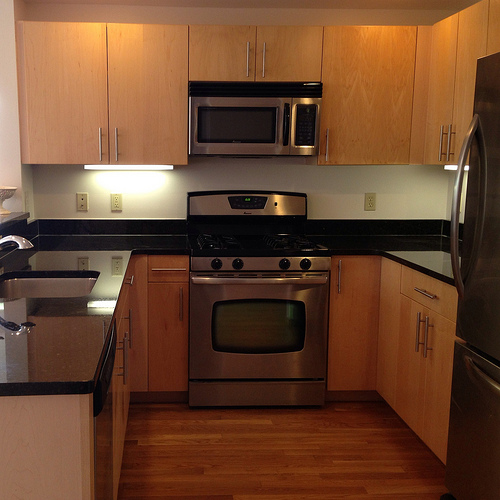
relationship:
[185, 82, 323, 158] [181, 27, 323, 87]
microwave under cabinets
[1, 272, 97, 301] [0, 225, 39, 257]
sink and faucet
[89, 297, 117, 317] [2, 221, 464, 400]
reflections on counter top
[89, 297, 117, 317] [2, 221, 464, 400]
reflection on counter top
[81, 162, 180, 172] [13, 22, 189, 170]
light under cabinet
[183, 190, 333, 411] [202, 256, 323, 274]
oven has knobs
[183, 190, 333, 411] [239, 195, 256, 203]
oven has a display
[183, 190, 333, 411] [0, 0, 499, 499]
stove in kitchen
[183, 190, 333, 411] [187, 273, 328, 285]
oven has handle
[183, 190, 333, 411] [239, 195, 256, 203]
stove time display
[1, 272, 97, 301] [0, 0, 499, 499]
sink on kitchen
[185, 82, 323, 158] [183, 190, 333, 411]
microwave above oven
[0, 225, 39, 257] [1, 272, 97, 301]
faucet above sink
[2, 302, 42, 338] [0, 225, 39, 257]
reflection of faucet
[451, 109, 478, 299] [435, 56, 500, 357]
handle to fridge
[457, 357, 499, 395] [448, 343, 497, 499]
handle to freezer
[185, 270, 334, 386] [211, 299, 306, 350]
door has window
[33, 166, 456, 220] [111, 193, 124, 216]
wall has outlet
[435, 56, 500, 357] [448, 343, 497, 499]
refrigerator with freezer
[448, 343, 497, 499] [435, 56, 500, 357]
freezer beneath refrigerator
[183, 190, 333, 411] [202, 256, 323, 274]
stove has knobs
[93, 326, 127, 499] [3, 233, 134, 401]
dishwasher under counter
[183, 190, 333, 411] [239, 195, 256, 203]
oven has a clock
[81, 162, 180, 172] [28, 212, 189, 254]
lighting under counter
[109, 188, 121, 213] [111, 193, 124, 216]
sockets part of outlet